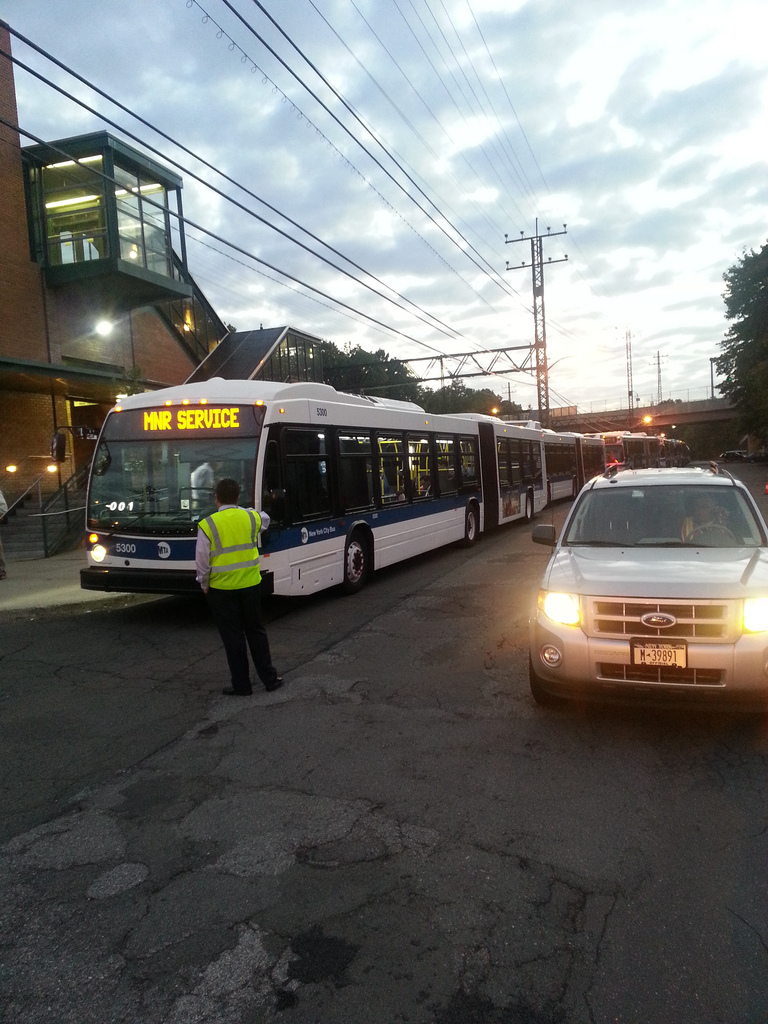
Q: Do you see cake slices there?
A: No, there are no cake slices.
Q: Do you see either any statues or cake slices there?
A: No, there are no cake slices or statues.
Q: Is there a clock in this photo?
A: No, there are no clocks.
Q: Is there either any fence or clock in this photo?
A: No, there are no clocks or fences.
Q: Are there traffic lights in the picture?
A: No, there are no traffic lights.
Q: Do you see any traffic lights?
A: No, there are no traffic lights.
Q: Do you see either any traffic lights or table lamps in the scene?
A: No, there are no traffic lights or table lamps.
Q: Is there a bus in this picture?
A: Yes, there is a bus.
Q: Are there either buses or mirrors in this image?
A: Yes, there is a bus.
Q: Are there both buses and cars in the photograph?
A: Yes, there are both a bus and a car.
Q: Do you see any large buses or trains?
A: Yes, there is a large bus.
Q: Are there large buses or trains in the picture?
A: Yes, there is a large bus.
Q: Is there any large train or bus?
A: Yes, there is a large bus.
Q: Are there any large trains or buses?
A: Yes, there is a large bus.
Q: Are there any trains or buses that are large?
A: Yes, the bus is large.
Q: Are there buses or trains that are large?
A: Yes, the bus is large.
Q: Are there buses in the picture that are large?
A: Yes, there is a large bus.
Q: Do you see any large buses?
A: Yes, there is a large bus.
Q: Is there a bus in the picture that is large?
A: Yes, there is a bus that is large.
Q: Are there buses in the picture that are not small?
A: Yes, there is a large bus.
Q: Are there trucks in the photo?
A: No, there are no trucks.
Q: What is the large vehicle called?
A: The vehicle is a bus.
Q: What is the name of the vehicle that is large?
A: The vehicle is a bus.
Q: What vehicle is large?
A: The vehicle is a bus.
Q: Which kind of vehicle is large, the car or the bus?
A: The bus is large.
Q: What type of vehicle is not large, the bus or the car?
A: The car is not large.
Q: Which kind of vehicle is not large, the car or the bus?
A: The car is not large.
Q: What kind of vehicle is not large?
A: The vehicle is a car.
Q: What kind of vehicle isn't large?
A: The vehicle is a car.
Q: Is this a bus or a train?
A: This is a bus.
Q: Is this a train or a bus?
A: This is a bus.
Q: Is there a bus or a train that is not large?
A: No, there is a bus but it is large.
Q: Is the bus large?
A: Yes, the bus is large.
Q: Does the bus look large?
A: Yes, the bus is large.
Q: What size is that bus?
A: The bus is large.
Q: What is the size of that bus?
A: The bus is large.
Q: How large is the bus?
A: The bus is large.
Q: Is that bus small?
A: No, the bus is large.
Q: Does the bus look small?
A: No, the bus is large.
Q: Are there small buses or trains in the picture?
A: No, there is a bus but it is large.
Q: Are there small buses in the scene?
A: No, there is a bus but it is large.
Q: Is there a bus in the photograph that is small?
A: No, there is a bus but it is large.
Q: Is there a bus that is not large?
A: No, there is a bus but it is large.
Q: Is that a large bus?
A: Yes, that is a large bus.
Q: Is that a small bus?
A: No, that is a large bus.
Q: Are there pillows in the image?
A: No, there are no pillows.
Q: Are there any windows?
A: Yes, there is a window.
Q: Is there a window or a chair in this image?
A: Yes, there is a window.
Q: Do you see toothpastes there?
A: No, there are no toothpastes.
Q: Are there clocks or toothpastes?
A: No, there are no toothpastes or clocks.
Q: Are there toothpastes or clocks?
A: No, there are no toothpastes or clocks.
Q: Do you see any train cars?
A: No, there are no train cars.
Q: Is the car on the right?
A: Yes, the car is on the right of the image.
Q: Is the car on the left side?
A: No, the car is on the right of the image.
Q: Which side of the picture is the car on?
A: The car is on the right of the image.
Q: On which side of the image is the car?
A: The car is on the right of the image.